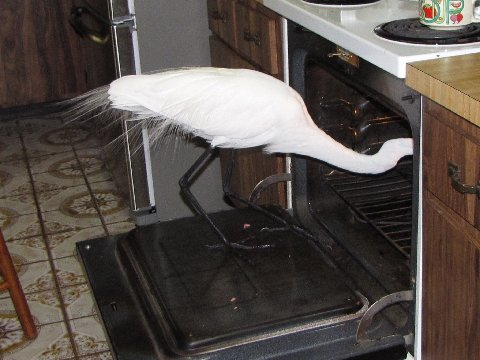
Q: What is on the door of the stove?
A: A large bird.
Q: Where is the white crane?
A: On the oven door.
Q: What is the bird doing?
A: Looking in the stove.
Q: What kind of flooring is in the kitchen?
A: Tile.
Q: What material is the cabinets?
A: Wood.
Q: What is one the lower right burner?
A: A mug.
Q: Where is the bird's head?
A: In the oven.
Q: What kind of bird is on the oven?
A: A crane.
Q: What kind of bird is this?
A: White bird.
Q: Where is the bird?
A: Oven door.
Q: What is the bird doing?
A: Sticking its neck in the oven.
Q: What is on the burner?
A: Coffee cup.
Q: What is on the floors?
A: Tiles.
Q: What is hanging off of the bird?
A: White hairs.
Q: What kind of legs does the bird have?
A: Black legs.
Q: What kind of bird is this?
A: Large white bird.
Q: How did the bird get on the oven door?
A: Left open.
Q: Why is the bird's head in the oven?
A: To look inside.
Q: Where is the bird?
A: Standing on an oven door.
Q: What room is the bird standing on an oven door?
A: Kitchen.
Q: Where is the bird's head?
A: Inside an oven.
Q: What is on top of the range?
A: A coffee cup.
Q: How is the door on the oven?
A: Open.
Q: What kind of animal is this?
A: Bird.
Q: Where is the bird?
A: Oven door.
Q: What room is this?
A: Kitchen.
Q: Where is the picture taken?
A: Kitchen.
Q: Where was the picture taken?
A: Home.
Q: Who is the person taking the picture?
A: No clue.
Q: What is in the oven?
A: Bird.